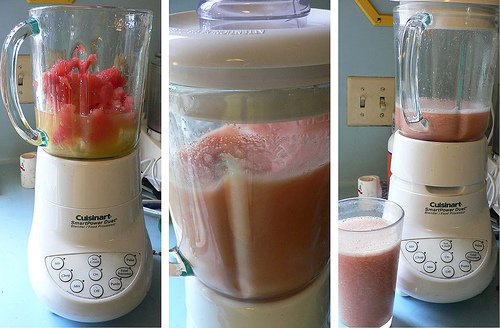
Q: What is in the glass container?
A: Liquid.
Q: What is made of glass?
A: The blender.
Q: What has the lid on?
A: The container.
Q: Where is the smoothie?
A: In the blender.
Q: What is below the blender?
A: Table.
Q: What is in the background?
A: Light switches.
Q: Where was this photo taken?
A: In a kitchen.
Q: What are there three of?
A: Three pictures.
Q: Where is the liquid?
A: In the blender.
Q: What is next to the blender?
A: A glass.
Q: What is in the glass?
A: A pink drink.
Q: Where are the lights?
A: Behind the blender.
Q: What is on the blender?
A: Words.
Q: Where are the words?
A: On the blender.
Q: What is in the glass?
A: A shake.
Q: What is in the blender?
A: Pureed fruit.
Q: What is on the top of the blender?
A: Lid cover.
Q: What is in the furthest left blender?
A: Unblended fruit.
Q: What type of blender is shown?
A: Cuisinart blender.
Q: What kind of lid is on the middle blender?
A: White and round lid.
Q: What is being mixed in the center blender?
A: Smoothie.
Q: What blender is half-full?
A: Rightmost blender.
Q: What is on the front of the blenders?
A: Buttons.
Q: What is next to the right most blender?
A: Glass with smoothie.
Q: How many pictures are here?
A: Three.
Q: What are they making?
A: Smoothies.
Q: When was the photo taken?
A: During daylight hours.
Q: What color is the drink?
A: Pink.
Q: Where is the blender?
A: On the counter.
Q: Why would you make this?
A: To have a refreshing drink.